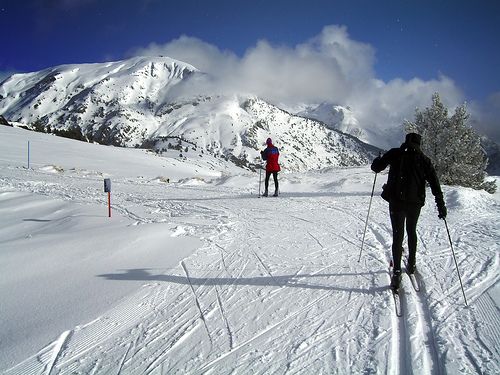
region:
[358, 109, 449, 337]
a person on snow skis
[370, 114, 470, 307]
a person holding ski poles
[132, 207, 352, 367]
tracks in the snow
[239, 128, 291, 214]
a person wearing a red and blue coat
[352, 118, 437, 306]
a person wearing black clothing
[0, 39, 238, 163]
a snow covered mountain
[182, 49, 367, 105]
white clouds in the sky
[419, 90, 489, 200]
a tree covered with snow and ice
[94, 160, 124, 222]
a post in the ground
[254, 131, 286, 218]
a person standing in the snow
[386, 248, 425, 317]
Person on skis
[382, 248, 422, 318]
Person is on skis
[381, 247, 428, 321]
Person wearing skis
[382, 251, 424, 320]
Person is wearing skis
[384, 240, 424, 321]
Person on white skis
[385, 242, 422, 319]
Person is on white skis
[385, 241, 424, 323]
Person wearing white skis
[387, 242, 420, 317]
Person is wearing white skis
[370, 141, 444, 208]
Person wearing a jacket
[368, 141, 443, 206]
Person is wearing a jacket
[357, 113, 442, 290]
man walking in snow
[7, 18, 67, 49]
white clouds in blue sky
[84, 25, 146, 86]
white clouds in blue sky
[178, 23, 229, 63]
white clouds in blue sky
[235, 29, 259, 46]
white clouds in blue sky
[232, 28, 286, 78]
white clouds in blue sky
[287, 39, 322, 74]
white clouds in blue sky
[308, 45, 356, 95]
white clouds in blue sky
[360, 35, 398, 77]
white clouds in blue sky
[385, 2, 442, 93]
white clouds in blue sky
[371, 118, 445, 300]
person skiing in white snow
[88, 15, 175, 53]
white clouds in blue sky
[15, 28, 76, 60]
white clouds in blue sky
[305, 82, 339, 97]
white clouds in blue sky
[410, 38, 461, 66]
white clouds in blue sky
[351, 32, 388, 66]
white clouds in blue sky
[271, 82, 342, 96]
white clouds in blue sky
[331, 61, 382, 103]
white clouds in blue sky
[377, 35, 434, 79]
white clouds in blue sky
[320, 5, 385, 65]
white clouds in blue sky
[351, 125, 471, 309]
Person walking with skis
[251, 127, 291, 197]
Person standing with skis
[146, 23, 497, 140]
a group of emerging clouds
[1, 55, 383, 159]
Large mountains in the background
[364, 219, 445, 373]
Track marks in the snow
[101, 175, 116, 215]
Red and white pole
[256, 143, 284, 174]
Red and black jacket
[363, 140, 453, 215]
Solid black jacket of skier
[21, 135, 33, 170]
Lonley blue pole in snow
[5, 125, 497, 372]
Pure white snowy hill